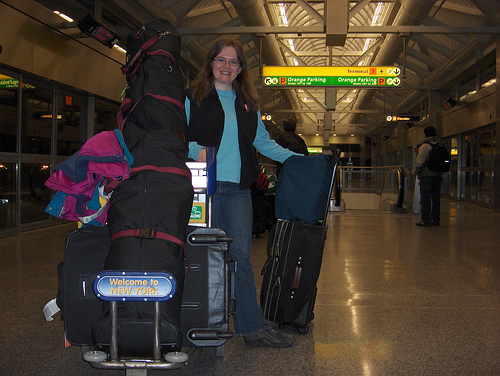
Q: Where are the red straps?
A: On the tall luggage.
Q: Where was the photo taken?
A: Transportation station.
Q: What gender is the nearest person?
A: Female.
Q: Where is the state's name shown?
A: On luggage caddy.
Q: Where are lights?
A: On the ceiling.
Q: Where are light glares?
A: On the floor.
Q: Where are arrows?
A: On signs.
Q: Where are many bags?
A: On a cart.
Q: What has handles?
A: The bags.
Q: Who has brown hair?
A: A woman.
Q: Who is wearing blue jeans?
A: The lady.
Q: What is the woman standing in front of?
A: Stack of luggage.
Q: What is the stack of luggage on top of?
A: Luggage cart.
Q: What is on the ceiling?
A: Lights.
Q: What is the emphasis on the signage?
A: Parking locations.